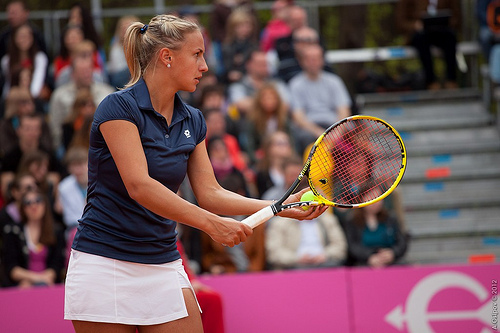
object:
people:
[61, 15, 204, 333]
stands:
[0, 1, 500, 331]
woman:
[64, 15, 330, 333]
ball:
[300, 190, 327, 211]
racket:
[223, 115, 409, 247]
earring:
[167, 64, 171, 70]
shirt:
[71, 77, 208, 266]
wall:
[0, 263, 500, 333]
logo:
[183, 129, 192, 139]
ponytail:
[117, 21, 147, 91]